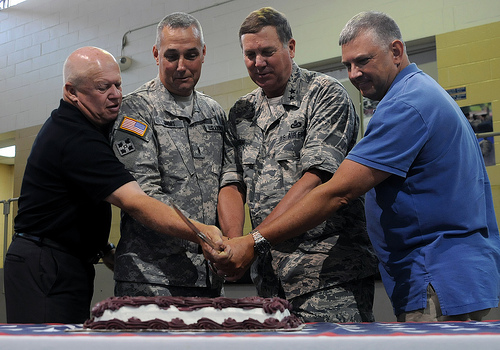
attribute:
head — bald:
[62, 45, 122, 126]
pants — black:
[1, 235, 98, 325]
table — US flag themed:
[8, 322, 442, 349]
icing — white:
[86, 285, 301, 339]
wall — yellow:
[6, 2, 494, 309]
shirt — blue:
[309, 67, 499, 320]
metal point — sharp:
[168, 199, 219, 251]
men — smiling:
[326, 16, 497, 320]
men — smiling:
[221, 15, 366, 308]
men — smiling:
[123, 20, 230, 286]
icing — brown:
[83, 294, 303, 330]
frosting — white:
[90, 303, 288, 324]